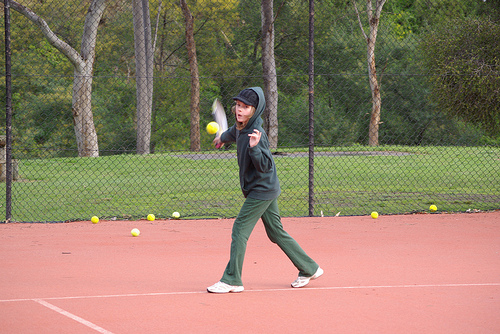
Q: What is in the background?
A: A row of trees.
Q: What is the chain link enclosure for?
A: A tennis court.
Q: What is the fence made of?
A: Metal.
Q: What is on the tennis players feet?
A: Tennis shoes.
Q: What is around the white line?
A: Red court.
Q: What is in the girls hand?
A: A tennis racket.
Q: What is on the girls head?
A: A cap and a hood.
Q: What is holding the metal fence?
A: A metal post.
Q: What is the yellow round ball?
A: A tennis ball.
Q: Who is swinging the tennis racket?
A: The girl.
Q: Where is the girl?
A: On a tennis court.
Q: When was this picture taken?
A: Daytime.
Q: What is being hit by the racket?
A: Tennis balls.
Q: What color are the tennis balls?
A: Yellow.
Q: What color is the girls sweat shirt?
A: Blue.